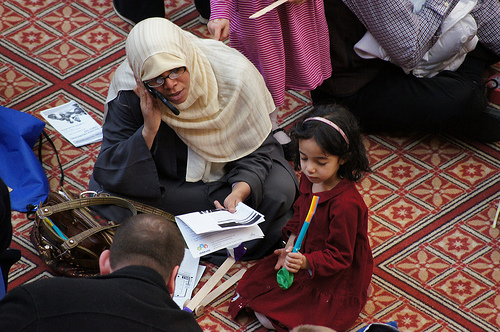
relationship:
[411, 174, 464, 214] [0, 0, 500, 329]
pattern on carpet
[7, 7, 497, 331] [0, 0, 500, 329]
pattern on carpet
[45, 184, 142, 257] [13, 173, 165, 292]
handle of a purse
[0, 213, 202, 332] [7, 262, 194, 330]
man wearing a shirt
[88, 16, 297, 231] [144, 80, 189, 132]
woman talking on phone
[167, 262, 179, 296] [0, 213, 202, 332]
ear of a man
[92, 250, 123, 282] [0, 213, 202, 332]
ear of a man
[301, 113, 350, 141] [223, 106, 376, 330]
head band on a child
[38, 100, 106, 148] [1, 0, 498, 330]
brochure on ground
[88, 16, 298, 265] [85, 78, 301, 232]
woman wearing a burka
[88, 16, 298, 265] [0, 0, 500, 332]
woman sitting on a carpet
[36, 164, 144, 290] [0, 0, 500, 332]
purse on a carpet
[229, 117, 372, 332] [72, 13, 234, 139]
child sitting next to a woman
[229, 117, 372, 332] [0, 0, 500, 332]
child sitting on a carpet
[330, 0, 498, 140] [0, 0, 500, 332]
man sitting on a carpet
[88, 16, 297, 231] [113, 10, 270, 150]
woman wearing a burka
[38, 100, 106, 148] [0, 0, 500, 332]
brochure on a carpet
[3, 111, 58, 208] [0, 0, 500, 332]
bag on a carpet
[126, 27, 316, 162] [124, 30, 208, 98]
cloth on head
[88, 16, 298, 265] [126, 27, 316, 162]
woman wearing cloth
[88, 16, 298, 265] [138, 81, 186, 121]
woman talking on phone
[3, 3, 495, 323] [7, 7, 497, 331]
floor has a pattern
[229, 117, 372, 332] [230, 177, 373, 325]
child wearing a dress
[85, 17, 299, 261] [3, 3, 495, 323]
person sitting on floor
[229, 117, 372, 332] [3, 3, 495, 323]
child sitting on floor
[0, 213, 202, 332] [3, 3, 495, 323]
man sitting on floor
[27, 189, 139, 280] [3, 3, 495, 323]
purse sitting on floor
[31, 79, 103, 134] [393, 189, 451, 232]
brochure on floor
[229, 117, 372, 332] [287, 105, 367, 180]
child has hair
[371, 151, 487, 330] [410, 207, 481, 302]
pattern on carpet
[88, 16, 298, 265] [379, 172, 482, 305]
woman sitting on floor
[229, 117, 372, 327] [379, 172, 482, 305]
child sitting on floor